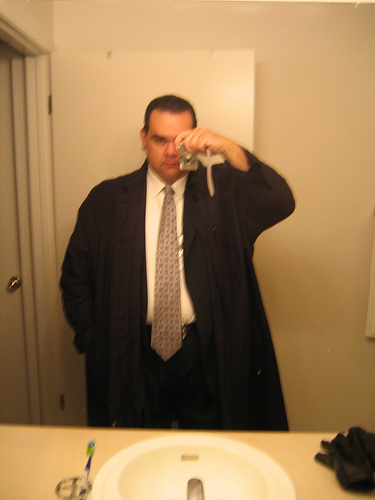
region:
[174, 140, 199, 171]
A silver camera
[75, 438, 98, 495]
A toothbrush in a holder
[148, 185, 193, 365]
a four in hand tie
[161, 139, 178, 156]
a man's nose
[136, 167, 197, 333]
a white collared shirt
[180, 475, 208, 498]
a spout for a faucet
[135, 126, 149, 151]
a man's left ear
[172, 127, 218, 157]
the man's fingers holding a camera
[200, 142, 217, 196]
a silver strap from the camera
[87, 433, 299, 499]
a white sink in front of the man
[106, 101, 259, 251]
man taking a picture of himself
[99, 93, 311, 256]
Man standing in front of mirror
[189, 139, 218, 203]
Strap that is connected to camera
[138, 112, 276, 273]
Picture is blurry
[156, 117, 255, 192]
Silver camera that man is holding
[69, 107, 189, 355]
Man wearing a black coat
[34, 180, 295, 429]
Long black coat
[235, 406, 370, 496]
black gloves on counter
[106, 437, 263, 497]
White bathroom sink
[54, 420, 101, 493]
Toothbrush in holder beside sink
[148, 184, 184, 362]
silver tie with squares on it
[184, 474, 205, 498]
silver faucet in the sink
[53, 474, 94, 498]
silver toothbrush holder by the sink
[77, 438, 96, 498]
blue, white and green toothbrush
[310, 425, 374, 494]
black gloves on the countertop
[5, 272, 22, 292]
silver doorknob on the white door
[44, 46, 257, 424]
white bathroom door behind the man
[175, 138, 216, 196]
silver camera in the man's hand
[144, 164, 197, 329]
white dress shirt on the man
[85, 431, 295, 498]
white sink in the countertop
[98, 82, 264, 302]
Man taking a picture of himself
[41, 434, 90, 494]
Toothbrush inside a cup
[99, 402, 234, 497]
The sink is white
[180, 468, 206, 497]
Silver faucet on the sink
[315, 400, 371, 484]
bag sitting on the counter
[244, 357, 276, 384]
Spot of dirt on mirror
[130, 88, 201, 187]
The man has slicked back hair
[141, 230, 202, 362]
Man wearing a tie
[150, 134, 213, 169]
the man is holding a camera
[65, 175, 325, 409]
Man wearing a black trench coat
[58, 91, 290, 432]
man taking selfie in bathroom mirror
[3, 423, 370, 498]
bathroom sink in front of man taking picture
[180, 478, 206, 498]
water faucet on sink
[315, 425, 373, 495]
black gloves of man laying on sink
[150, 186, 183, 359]
grey tie of man taking picture of himself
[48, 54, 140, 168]
door behind man taking selfie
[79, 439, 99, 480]
toothbrush in holder on sink area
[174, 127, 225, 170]
hand of man with camera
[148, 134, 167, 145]
one eye of man looking into camera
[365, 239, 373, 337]
towel hanging in back of man taking selfie